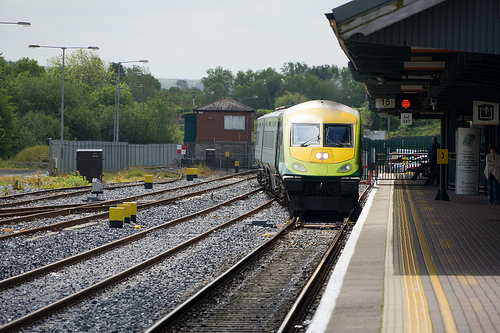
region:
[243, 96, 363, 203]
yellow and black train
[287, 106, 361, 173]
front of yellow train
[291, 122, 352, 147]
front windows of train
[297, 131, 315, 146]
black window wipers on train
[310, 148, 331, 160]
front lights of train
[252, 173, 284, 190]
wheels on bottom of train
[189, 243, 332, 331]
metal train tracks on the ground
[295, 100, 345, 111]
white roof of train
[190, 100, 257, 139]
small brick building in background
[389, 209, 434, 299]
yellow lines on platform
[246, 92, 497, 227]
green and yellow train crossing tracks by outdoor station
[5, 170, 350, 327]
metal rails crossing over gravel ground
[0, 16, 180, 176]
gray wall and lamp posts at end of tracks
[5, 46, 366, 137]
grey sky over trees in back of train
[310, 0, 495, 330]
thick roof slanting over striped platform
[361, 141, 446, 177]
cars behind fence at end of platform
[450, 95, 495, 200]
woman in shade near large and small signs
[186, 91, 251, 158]
worn roof on grey and red building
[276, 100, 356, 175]
two dark windows over lit and unlit headlights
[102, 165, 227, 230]
short yellow and black markers along tracks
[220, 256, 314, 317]
railroad rails and ties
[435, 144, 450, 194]
a sign on a post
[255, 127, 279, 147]
windows on train cars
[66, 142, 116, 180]
outdoor electrical box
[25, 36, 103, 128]
two streetlights on one pole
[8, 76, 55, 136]
trees with green leaves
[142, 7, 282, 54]
an area of clear sky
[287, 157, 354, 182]
headlights on a train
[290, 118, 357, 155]
windshield on a train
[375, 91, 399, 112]
a white sign with black number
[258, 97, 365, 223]
The train is yellow.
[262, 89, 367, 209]
The edge of the train is green.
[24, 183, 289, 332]
Many tracks are at the train station.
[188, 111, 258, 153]
The building is brown.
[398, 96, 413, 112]
The light is red.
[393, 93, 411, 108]
The light is on.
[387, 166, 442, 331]
The painted lines are yellow.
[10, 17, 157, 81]
The street lights are off.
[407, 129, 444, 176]
They are waiting at the train station.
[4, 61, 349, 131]
The trees are leafy.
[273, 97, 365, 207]
the green and yellow front of a train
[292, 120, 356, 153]
the windshields of a train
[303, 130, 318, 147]
a windshield wiper on a window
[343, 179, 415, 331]
a train loading platform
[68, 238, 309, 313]
train tracks in gravel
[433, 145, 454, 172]
a sign on a post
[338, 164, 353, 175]
the left headlight on a train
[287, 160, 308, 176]
the right headlight on a train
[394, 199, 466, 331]
yellow painted lines on a train loading platform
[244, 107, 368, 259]
a train on the tracks